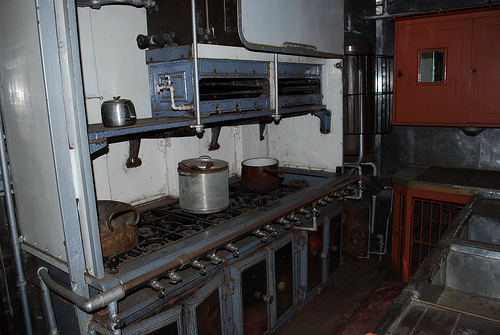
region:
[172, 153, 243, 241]
silver metal pot on stove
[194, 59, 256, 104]
silver metal microwave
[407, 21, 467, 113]
many items in the kitchen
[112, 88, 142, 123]
many items in the kitchen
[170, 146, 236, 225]
a pot color silver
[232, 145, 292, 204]
black pot with inside white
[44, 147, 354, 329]
a commercial stove color silver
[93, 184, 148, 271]
the pot is rusted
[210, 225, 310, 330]
the cabinets has gray door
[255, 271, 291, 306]
the cabinets have knobs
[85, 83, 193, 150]
a pot on top a shelf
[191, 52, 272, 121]
door of an oven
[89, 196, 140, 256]
cast iron pot on the stove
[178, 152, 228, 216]
gray pot with lid on the stove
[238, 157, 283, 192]
pot with no lid on the stove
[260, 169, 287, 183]
black handle on the pot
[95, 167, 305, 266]
burners on the stove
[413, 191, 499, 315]
sink basins on the right side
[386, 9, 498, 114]
orange cabinets above the counter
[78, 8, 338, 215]
white walls behind the stove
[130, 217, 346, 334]
cabinet doors under the stove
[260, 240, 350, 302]
knobs on the cabinet doors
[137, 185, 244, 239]
the stove is rusty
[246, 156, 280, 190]
the pot is brown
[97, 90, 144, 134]
kettle on the shelf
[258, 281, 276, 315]
knob on the door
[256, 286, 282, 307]
the knob is brown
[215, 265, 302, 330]
the cabinets are rusted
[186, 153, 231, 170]
lid on the pot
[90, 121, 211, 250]
shelf above the stove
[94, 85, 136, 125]
the kettle is silver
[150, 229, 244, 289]
knobs below the stove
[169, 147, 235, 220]
a pot on a stove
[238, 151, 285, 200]
the pot is color black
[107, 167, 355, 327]
the stove is old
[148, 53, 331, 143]
two old ovens of metal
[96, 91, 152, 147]
a pot on a shelf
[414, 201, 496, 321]
the sink is old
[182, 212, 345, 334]
cabinets below the stove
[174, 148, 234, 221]
a silver tall pot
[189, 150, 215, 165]
handle on the lid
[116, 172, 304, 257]
grates on the stove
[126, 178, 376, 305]
nobs on the stove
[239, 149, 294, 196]
a burgundy pot on stove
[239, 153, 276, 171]
white inside of pot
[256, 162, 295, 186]
handle of the pot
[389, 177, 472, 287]
a red glass door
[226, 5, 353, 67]
a pipe on the wall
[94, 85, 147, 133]
a small silver pot